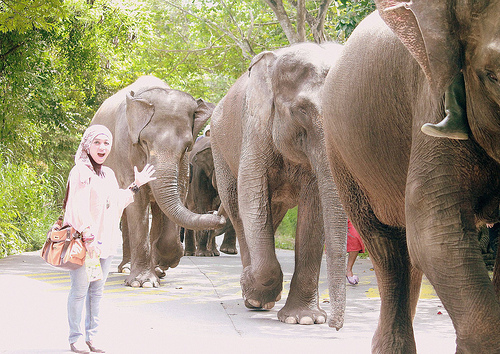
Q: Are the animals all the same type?
A: Yes, all the animals are elephants.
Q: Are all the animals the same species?
A: Yes, all the animals are elephants.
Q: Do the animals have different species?
A: No, all the animals are elephants.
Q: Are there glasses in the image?
A: No, there are no glasses.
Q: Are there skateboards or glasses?
A: No, there are no glasses or skateboards.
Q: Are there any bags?
A: Yes, there is a bag.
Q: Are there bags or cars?
A: Yes, there is a bag.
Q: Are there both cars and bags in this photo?
A: No, there is a bag but no cars.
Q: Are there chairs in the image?
A: No, there are no chairs.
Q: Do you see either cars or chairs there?
A: No, there are no chairs or cars.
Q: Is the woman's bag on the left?
A: Yes, the bag is on the left of the image.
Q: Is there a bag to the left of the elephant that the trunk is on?
A: Yes, there is a bag to the left of the elephant.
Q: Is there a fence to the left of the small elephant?
A: No, there is a bag to the left of the elephant.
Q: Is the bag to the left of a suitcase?
A: No, the bag is to the left of the elephant.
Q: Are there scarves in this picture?
A: Yes, there is a scarf.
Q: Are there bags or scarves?
A: Yes, there is a scarf.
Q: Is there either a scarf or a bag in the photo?
A: Yes, there is a scarf.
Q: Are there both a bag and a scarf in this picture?
A: Yes, there are both a scarf and a bag.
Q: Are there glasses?
A: No, there are no glasses.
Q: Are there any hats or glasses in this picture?
A: No, there are no glasses or hats.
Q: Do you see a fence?
A: No, there are no fences.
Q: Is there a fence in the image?
A: No, there are no fences.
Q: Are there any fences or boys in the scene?
A: No, there are no fences or boys.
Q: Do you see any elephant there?
A: Yes, there are elephants.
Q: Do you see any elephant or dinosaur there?
A: Yes, there are elephants.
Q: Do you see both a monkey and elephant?
A: No, there are elephants but no monkeys.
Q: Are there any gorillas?
A: No, there are no gorillas.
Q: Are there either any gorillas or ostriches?
A: No, there are no gorillas or ostriches.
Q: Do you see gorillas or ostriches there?
A: No, there are no gorillas or ostriches.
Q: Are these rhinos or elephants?
A: These are elephants.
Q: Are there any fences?
A: No, there are no fences.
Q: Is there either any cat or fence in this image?
A: No, there are no fences or cats.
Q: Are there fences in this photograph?
A: No, there are no fences.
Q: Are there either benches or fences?
A: No, there are no fences or benches.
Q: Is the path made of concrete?
A: Yes, the path is made of concrete.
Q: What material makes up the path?
A: The path is made of cement.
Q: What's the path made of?
A: The path is made of concrete.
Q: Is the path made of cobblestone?
A: No, the path is made of concrete.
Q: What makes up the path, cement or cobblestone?
A: The path is made of cement.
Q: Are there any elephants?
A: Yes, there is an elephant.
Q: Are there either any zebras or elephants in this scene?
A: Yes, there is an elephant.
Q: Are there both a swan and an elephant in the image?
A: No, there is an elephant but no swans.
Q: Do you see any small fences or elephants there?
A: Yes, there is a small elephant.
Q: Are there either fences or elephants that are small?
A: Yes, the elephant is small.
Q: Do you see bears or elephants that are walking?
A: Yes, the elephant is walking.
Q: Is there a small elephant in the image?
A: Yes, there is a small elephant.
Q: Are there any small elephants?
A: Yes, there is a small elephant.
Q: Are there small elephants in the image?
A: Yes, there is a small elephant.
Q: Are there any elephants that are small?
A: Yes, there is an elephant that is small.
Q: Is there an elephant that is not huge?
A: Yes, there is a small elephant.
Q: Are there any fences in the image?
A: No, there are no fences.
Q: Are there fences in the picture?
A: No, there are no fences.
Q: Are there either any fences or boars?
A: No, there are no fences or boars.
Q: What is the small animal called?
A: The animal is an elephant.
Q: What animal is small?
A: The animal is an elephant.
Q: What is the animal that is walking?
A: The animal is an elephant.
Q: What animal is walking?
A: The animal is an elephant.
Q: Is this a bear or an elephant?
A: This is an elephant.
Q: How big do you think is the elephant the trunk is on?
A: The elephant is small.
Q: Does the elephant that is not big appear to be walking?
A: Yes, the elephant is walking.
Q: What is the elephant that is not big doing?
A: The elephant is walking.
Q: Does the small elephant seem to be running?
A: No, the elephant is walking.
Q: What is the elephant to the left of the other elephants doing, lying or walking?
A: The elephant is walking.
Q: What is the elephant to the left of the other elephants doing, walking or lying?
A: The elephant is walking.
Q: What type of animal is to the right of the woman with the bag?
A: The animal is an elephant.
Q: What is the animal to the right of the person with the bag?
A: The animal is an elephant.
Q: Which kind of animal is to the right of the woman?
A: The animal is an elephant.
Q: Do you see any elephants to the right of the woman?
A: Yes, there is an elephant to the right of the woman.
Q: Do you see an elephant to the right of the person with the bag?
A: Yes, there is an elephant to the right of the woman.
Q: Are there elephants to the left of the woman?
A: No, the elephant is to the right of the woman.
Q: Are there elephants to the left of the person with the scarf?
A: No, the elephant is to the right of the woman.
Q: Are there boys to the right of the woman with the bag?
A: No, there is an elephant to the right of the woman.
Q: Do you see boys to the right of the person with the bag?
A: No, there is an elephant to the right of the woman.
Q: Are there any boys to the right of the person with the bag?
A: No, there is an elephant to the right of the woman.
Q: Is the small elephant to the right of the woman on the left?
A: Yes, the elephant is to the right of the woman.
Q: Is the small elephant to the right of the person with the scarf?
A: Yes, the elephant is to the right of the woman.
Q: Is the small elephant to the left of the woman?
A: No, the elephant is to the right of the woman.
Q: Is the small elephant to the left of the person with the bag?
A: No, the elephant is to the right of the woman.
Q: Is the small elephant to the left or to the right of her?
A: The elephant is to the right of the woman.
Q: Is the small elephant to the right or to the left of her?
A: The elephant is to the right of the woman.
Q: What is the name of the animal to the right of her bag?
A: The animal is an elephant.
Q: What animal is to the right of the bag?
A: The animal is an elephant.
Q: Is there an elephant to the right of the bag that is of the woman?
A: Yes, there is an elephant to the right of the bag.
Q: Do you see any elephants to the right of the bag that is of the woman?
A: Yes, there is an elephant to the right of the bag.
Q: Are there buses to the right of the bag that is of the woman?
A: No, there is an elephant to the right of the bag.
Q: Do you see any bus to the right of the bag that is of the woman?
A: No, there is an elephant to the right of the bag.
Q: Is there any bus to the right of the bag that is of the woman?
A: No, there is an elephant to the right of the bag.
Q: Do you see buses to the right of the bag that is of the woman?
A: No, there is an elephant to the right of the bag.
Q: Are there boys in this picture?
A: No, there are no boys.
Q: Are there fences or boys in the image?
A: No, there are no boys or fences.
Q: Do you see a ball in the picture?
A: No, there are no balls.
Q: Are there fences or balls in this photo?
A: No, there are no balls or fences.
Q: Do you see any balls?
A: No, there are no balls.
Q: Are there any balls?
A: No, there are no balls.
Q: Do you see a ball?
A: No, there are no balls.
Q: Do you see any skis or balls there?
A: No, there are no balls or skis.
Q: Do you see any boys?
A: No, there are no boys.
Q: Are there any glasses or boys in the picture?
A: No, there are no boys or glasses.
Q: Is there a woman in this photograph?
A: Yes, there is a woman.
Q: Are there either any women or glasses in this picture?
A: Yes, there is a woman.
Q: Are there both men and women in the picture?
A: No, there is a woman but no men.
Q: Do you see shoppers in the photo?
A: No, there are no shoppers.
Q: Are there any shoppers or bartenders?
A: No, there are no shoppers or bartenders.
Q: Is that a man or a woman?
A: That is a woman.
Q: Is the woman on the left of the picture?
A: Yes, the woman is on the left of the image.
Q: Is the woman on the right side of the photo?
A: No, the woman is on the left of the image.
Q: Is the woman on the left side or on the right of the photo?
A: The woman is on the left of the image.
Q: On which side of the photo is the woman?
A: The woman is on the left of the image.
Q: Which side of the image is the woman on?
A: The woman is on the left of the image.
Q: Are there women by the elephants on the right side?
A: Yes, there is a woman by the elephants.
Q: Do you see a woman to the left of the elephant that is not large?
A: Yes, there is a woman to the left of the elephant.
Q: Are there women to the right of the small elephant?
A: No, the woman is to the left of the elephant.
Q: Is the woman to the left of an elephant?
A: Yes, the woman is to the left of an elephant.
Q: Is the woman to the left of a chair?
A: No, the woman is to the left of an elephant.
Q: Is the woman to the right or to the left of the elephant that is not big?
A: The woman is to the left of the elephant.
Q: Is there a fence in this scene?
A: No, there are no fences.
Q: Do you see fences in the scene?
A: No, there are no fences.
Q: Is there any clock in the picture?
A: No, there are no clocks.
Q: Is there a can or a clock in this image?
A: No, there are no clocks or cans.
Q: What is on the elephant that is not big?
A: The trunk is on the elephant.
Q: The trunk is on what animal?
A: The trunk is on the elephant.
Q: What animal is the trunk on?
A: The trunk is on the elephant.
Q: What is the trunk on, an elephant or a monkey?
A: The trunk is on an elephant.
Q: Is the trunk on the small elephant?
A: Yes, the trunk is on the elephant.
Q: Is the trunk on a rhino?
A: No, the trunk is on the elephant.